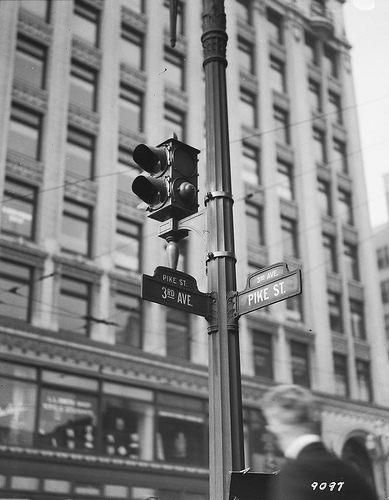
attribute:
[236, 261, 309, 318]
street sign — attached to pole, for pike st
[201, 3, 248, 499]
post — tall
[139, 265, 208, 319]
street sign — also for pike st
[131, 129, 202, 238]
street light — in the photo, in center of pole, old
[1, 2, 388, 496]
building — tall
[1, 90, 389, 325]
wires — in the air, telephone lines, power lines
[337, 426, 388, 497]
entrance — arched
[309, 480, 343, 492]
9097 — under man's head, written in white, by the man, below the building, on photo, marked on the photo, under sign on right, under the wires, under the man, on the right side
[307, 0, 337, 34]
balcony — in far right side